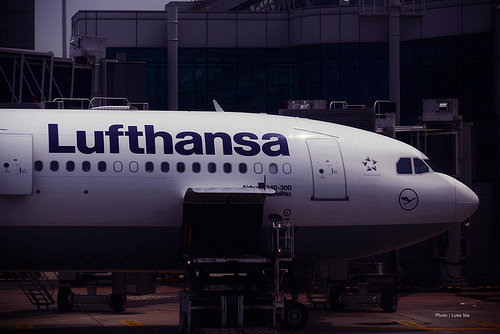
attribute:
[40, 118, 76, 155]
letter — blue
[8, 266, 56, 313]
stairs — metal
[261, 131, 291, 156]
letter — blue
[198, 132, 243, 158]
letter — blue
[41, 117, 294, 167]
lufthansa — commercial airplane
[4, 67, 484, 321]
plane — blue, white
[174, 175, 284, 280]
compartment — open lugggage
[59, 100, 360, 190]
letter — blue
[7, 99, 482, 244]
plane — white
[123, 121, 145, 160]
letter — blue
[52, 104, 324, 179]
logo — Circular, Lufthansa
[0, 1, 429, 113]
hangar — airplane